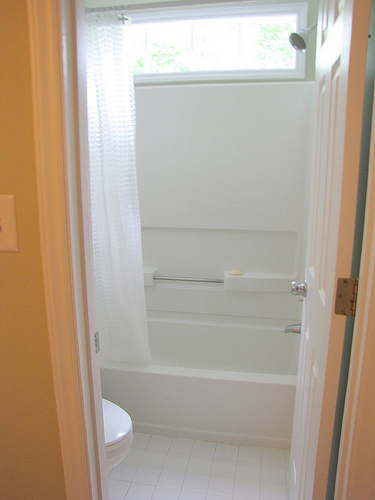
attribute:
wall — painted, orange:
[0, 0, 64, 498]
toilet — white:
[99, 396, 134, 481]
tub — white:
[99, 303, 295, 446]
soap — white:
[224, 267, 242, 275]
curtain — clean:
[84, 5, 155, 364]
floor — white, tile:
[103, 428, 287, 497]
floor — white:
[129, 447, 283, 497]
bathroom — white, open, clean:
[85, 0, 312, 498]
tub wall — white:
[126, 361, 287, 446]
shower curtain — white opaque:
[80, 11, 151, 362]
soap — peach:
[227, 269, 241, 278]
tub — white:
[105, 310, 288, 447]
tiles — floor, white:
[160, 454, 232, 492]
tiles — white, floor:
[161, 450, 238, 490]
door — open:
[276, 1, 358, 498]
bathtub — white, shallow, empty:
[102, 309, 298, 447]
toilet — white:
[103, 398, 132, 464]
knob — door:
[289, 281, 306, 296]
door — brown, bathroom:
[282, 0, 363, 498]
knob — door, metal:
[287, 280, 307, 298]